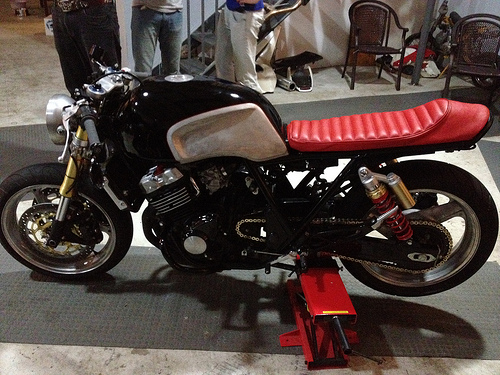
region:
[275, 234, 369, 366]
a red motorcycle ramp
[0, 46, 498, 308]
a red vintage motorcycle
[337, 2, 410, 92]
a steel 4 legged chair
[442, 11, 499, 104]
a steel four legged chair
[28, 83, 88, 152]
a motorcycle head lamp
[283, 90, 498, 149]
backseat of the motorcycle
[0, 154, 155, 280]
front wheel of motorcycle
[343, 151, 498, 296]
back wheel of motorcycle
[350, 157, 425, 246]
motorcycle strut shock absorption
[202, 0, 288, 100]
a person wearing beige pants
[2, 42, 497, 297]
a parked black motorcycle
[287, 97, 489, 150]
a red leather motorcycle seat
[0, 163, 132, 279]
a motorcycle front tire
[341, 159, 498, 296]
a motorcycle rear tire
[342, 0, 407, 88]
a black and brown chair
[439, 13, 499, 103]
a black and brown chair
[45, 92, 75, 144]
a motorcycle headlight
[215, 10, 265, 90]
a pair of white pants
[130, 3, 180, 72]
a pair of blue jeans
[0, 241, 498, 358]
a grey floor mat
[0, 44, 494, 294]
THERE ARE A MOTER BIKE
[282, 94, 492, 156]
THERE ARE A MOTER BIKE RED SIT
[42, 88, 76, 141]
THERE ARE A MOTER BIKE SILVER LIGHT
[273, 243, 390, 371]
THERE ARE A RED LIFTER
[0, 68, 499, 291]
THERE ARE A BLACK AND RED MOTER BIKE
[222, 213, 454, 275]
THERE ARE A MOTER BIKE CHAIN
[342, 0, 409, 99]
THERE ARE A BROWN CHAIR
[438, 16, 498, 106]
THERE ARE ANOTHER BROWN CHAIR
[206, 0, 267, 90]
A PERSON WITH WHITE PANTS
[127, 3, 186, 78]
A PERSON WITH BLUE JEAN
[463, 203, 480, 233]
part of a wheel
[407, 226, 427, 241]
part of a chain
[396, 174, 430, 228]
edge of a wheel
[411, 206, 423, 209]
part of a spoke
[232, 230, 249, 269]
part of an engine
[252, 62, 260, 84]
part of a trouser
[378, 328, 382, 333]
part of a shadow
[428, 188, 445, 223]
edge of a wheel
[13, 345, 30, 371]
Small part of grey pavement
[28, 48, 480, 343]
Small black and red bike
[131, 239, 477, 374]
Black shadow on ground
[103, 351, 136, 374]
Small part of grey pavement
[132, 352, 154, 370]
Small part of grey pavement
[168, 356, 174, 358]
Small part of grey pavement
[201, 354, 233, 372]
Small part of grey pavement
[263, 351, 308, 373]
Small part of grey pavement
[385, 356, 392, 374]
Small part of grey pavement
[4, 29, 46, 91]
Small part of grey pavement